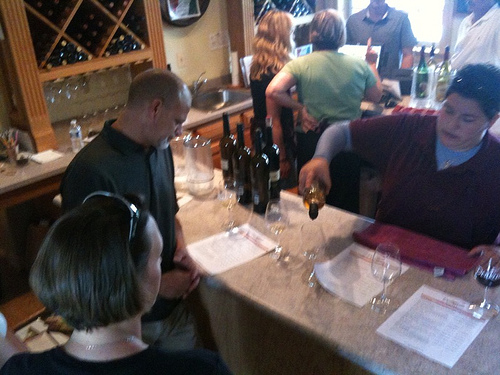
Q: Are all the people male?
A: No, they are both male and female.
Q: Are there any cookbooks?
A: No, there are no cookbooks.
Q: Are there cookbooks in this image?
A: No, there are no cookbooks.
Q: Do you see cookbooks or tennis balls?
A: No, there are no cookbooks or tennis balls.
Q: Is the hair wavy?
A: Yes, the hair is wavy.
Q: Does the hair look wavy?
A: Yes, the hair is wavy.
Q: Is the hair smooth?
A: No, the hair is wavy.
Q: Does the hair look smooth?
A: No, the hair is wavy.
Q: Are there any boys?
A: No, there are no boys.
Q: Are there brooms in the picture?
A: No, there are no brooms.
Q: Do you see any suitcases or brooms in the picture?
A: No, there are no brooms or suitcases.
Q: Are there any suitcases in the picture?
A: No, there are no suitcases.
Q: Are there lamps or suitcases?
A: No, there are no suitcases or lamps.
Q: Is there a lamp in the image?
A: No, there are no lamps.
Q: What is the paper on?
A: The paper is on the counter.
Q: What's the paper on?
A: The paper is on the counter.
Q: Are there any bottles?
A: Yes, there is a bottle.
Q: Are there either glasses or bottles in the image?
A: Yes, there is a bottle.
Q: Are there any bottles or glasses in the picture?
A: Yes, there is a bottle.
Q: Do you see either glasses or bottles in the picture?
A: Yes, there is a bottle.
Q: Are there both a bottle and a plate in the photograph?
A: No, there is a bottle but no plates.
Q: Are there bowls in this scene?
A: No, there are no bowls.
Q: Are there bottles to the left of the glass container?
A: Yes, there is a bottle to the left of the container.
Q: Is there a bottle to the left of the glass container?
A: Yes, there is a bottle to the left of the container.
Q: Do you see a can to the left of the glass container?
A: No, there is a bottle to the left of the container.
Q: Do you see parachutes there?
A: No, there are no parachutes.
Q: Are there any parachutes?
A: No, there are no parachutes.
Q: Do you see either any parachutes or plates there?
A: No, there are no parachutes or plates.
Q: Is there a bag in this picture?
A: No, there are no bags.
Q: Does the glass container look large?
A: Yes, the container is large.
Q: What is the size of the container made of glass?
A: The container is large.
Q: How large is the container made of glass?
A: The container is large.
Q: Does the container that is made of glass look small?
A: No, the container is large.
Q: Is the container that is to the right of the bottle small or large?
A: The container is large.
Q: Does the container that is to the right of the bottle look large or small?
A: The container is large.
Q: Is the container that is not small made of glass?
A: Yes, the container is made of glass.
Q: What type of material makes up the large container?
A: The container is made of glass.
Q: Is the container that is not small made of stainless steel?
A: No, the container is made of glass.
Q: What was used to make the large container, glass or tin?
A: The container is made of glass.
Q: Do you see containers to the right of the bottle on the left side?
A: Yes, there is a container to the right of the bottle.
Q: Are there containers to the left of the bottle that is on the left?
A: No, the container is to the right of the bottle.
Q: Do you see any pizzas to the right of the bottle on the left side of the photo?
A: No, there is a container to the right of the bottle.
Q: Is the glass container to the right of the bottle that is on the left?
A: Yes, the container is to the right of the bottle.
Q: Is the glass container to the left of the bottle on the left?
A: No, the container is to the right of the bottle.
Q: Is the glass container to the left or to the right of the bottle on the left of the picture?
A: The container is to the right of the bottle.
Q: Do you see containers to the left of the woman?
A: Yes, there is a container to the left of the woman.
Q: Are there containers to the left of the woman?
A: Yes, there is a container to the left of the woman.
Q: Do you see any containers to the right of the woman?
A: No, the container is to the left of the woman.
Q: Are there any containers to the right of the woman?
A: No, the container is to the left of the woman.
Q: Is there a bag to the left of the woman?
A: No, there is a container to the left of the woman.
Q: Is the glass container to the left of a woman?
A: Yes, the container is to the left of a woman.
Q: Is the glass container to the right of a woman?
A: No, the container is to the left of a woman.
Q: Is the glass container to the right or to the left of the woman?
A: The container is to the left of the woman.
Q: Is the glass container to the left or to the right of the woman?
A: The container is to the left of the woman.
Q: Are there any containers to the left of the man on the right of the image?
A: Yes, there is a container to the left of the man.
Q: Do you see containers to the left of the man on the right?
A: Yes, there is a container to the left of the man.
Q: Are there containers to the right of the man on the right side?
A: No, the container is to the left of the man.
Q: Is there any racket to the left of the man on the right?
A: No, there is a container to the left of the man.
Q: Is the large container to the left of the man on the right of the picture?
A: Yes, the container is to the left of the man.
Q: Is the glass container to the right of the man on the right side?
A: No, the container is to the left of the man.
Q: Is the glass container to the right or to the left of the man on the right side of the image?
A: The container is to the left of the man.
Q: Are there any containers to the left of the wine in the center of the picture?
A: Yes, there is a container to the left of the wine.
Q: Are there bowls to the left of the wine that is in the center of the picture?
A: No, there is a container to the left of the wine.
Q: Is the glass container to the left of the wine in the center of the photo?
A: Yes, the container is to the left of the wine.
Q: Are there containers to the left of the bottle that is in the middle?
A: Yes, there is a container to the left of the bottle.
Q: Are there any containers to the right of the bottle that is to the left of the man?
A: No, the container is to the left of the bottle.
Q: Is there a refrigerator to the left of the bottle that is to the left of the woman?
A: No, there is a container to the left of the bottle.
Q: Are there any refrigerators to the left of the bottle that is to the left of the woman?
A: No, there is a container to the left of the bottle.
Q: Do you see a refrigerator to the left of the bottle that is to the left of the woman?
A: No, there is a container to the left of the bottle.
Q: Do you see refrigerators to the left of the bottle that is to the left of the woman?
A: No, there is a container to the left of the bottle.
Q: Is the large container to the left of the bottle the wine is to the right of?
A: Yes, the container is to the left of the bottle.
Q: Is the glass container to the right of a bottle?
A: No, the container is to the left of a bottle.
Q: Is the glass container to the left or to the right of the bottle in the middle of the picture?
A: The container is to the left of the bottle.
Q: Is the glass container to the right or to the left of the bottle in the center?
A: The container is to the left of the bottle.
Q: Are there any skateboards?
A: No, there are no skateboards.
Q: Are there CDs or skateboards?
A: No, there are no skateboards or cds.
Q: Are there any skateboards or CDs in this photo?
A: No, there are no skateboards or cds.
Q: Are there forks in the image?
A: No, there are no forks.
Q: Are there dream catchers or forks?
A: No, there are no forks or dream catchers.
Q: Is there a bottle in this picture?
A: Yes, there is a bottle.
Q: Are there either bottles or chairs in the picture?
A: Yes, there is a bottle.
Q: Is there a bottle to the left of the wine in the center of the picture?
A: Yes, there is a bottle to the left of the wine.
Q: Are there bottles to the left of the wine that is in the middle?
A: Yes, there is a bottle to the left of the wine.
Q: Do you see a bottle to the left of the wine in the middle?
A: Yes, there is a bottle to the left of the wine.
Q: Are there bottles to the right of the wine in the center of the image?
A: No, the bottle is to the left of the wine.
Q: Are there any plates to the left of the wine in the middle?
A: No, there is a bottle to the left of the wine.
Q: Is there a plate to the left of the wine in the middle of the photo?
A: No, there is a bottle to the left of the wine.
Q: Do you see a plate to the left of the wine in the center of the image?
A: No, there is a bottle to the left of the wine.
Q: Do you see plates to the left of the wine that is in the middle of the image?
A: No, there is a bottle to the left of the wine.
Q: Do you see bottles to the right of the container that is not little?
A: Yes, there is a bottle to the right of the container.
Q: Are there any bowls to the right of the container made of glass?
A: No, there is a bottle to the right of the container.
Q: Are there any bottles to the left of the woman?
A: Yes, there is a bottle to the left of the woman.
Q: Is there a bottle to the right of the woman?
A: No, the bottle is to the left of the woman.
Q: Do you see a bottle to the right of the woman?
A: No, the bottle is to the left of the woman.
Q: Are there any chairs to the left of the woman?
A: No, there is a bottle to the left of the woman.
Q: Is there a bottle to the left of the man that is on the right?
A: Yes, there is a bottle to the left of the man.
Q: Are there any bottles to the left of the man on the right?
A: Yes, there is a bottle to the left of the man.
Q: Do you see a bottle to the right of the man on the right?
A: No, the bottle is to the left of the man.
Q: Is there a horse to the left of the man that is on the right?
A: No, there is a bottle to the left of the man.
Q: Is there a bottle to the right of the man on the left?
A: Yes, there is a bottle to the right of the man.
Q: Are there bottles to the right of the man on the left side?
A: Yes, there is a bottle to the right of the man.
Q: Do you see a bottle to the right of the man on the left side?
A: Yes, there is a bottle to the right of the man.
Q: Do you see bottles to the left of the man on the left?
A: No, the bottle is to the right of the man.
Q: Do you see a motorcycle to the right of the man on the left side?
A: No, there is a bottle to the right of the man.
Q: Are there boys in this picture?
A: No, there are no boys.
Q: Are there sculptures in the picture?
A: No, there are no sculptures.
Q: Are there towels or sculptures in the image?
A: No, there are no sculptures or towels.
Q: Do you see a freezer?
A: No, there are no refrigerators.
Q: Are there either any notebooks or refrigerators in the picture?
A: No, there are no refrigerators or notebooks.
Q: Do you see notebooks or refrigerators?
A: No, there are no refrigerators or notebooks.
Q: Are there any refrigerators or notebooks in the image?
A: No, there are no refrigerators or notebooks.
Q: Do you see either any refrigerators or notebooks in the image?
A: No, there are no refrigerators or notebooks.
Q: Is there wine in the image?
A: Yes, there is wine.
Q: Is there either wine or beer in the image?
A: Yes, there is wine.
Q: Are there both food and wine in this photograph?
A: No, there is wine but no food.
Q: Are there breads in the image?
A: No, there are no breads.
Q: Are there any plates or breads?
A: No, there are no breads or plates.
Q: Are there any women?
A: Yes, there is a woman.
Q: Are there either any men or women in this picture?
A: Yes, there is a woman.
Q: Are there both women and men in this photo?
A: Yes, there are both a woman and a man.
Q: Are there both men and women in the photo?
A: Yes, there are both a woman and a man.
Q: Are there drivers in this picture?
A: No, there are no drivers.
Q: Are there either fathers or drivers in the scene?
A: No, there are no drivers or fathers.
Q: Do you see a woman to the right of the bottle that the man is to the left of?
A: Yes, there is a woman to the right of the bottle.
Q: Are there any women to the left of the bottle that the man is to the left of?
A: No, the woman is to the right of the bottle.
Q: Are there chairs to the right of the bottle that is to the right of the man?
A: No, there is a woman to the right of the bottle.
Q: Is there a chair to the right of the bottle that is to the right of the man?
A: No, there is a woman to the right of the bottle.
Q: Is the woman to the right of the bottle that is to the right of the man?
A: Yes, the woman is to the right of the bottle.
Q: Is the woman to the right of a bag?
A: No, the woman is to the right of the bottle.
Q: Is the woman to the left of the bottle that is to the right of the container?
A: No, the woman is to the right of the bottle.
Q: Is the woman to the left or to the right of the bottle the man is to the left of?
A: The woman is to the right of the bottle.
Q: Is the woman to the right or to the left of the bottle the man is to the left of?
A: The woman is to the right of the bottle.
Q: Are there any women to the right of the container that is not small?
A: Yes, there is a woman to the right of the container.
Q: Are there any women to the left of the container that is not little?
A: No, the woman is to the right of the container.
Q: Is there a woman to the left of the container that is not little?
A: No, the woman is to the right of the container.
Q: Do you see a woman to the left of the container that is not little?
A: No, the woman is to the right of the container.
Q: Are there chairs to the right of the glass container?
A: No, there is a woman to the right of the container.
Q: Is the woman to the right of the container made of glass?
A: Yes, the woman is to the right of the container.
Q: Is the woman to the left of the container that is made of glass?
A: No, the woman is to the right of the container.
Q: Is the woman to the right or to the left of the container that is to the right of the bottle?
A: The woman is to the right of the container.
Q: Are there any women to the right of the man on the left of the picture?
A: Yes, there is a woman to the right of the man.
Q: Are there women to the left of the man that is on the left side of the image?
A: No, the woman is to the right of the man.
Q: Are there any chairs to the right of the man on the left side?
A: No, there is a woman to the right of the man.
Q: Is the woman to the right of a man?
A: Yes, the woman is to the right of a man.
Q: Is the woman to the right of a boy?
A: No, the woman is to the right of a man.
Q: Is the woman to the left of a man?
A: No, the woman is to the right of a man.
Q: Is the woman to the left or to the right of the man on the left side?
A: The woman is to the right of the man.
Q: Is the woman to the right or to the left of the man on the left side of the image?
A: The woman is to the right of the man.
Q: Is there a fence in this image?
A: No, there are no fences.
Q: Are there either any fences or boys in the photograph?
A: No, there are no fences or boys.